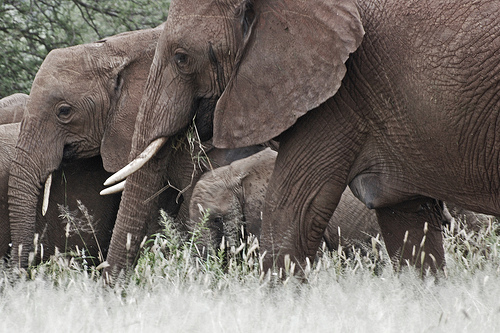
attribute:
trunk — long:
[96, 70, 193, 286]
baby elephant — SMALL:
[191, 149, 388, 280]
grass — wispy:
[157, 205, 222, 284]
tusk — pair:
[101, 136, 163, 185]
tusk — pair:
[98, 181, 125, 195]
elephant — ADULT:
[4, 15, 279, 290]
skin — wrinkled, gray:
[393, 35, 483, 157]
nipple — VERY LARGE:
[365, 203, 374, 211]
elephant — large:
[92, 0, 499, 283]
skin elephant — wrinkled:
[381, 13, 493, 198]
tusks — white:
[101, 136, 167, 186]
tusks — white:
[100, 180, 126, 197]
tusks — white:
[39, 167, 54, 217]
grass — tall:
[4, 200, 496, 330]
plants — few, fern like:
[10, 194, 497, 329]